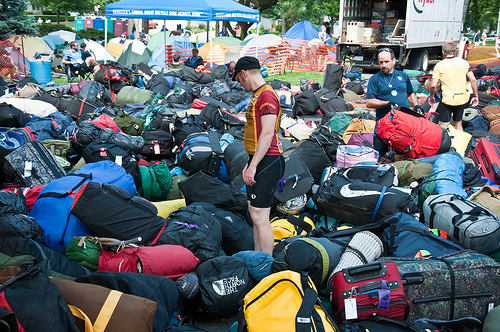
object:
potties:
[112, 15, 127, 36]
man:
[227, 52, 287, 256]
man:
[362, 42, 420, 159]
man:
[425, 40, 481, 138]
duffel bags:
[4, 137, 66, 187]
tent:
[197, 0, 234, 74]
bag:
[239, 272, 334, 330]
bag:
[422, 192, 499, 255]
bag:
[157, 202, 225, 264]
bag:
[178, 126, 225, 176]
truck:
[333, 0, 468, 72]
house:
[280, 220, 357, 281]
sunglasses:
[375, 46, 393, 53]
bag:
[323, 61, 347, 96]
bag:
[2, 266, 82, 329]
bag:
[330, 259, 412, 316]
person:
[480, 27, 488, 46]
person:
[472, 30, 481, 47]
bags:
[195, 249, 256, 319]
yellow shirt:
[431, 58, 472, 105]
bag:
[322, 172, 412, 226]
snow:
[314, 177, 416, 223]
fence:
[163, 35, 345, 90]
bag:
[375, 109, 452, 160]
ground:
[11, 62, 498, 324]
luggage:
[72, 174, 173, 243]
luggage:
[111, 84, 161, 106]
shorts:
[246, 151, 286, 205]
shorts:
[432, 98, 470, 124]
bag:
[50, 276, 157, 331]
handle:
[349, 263, 384, 276]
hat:
[230, 55, 262, 81]